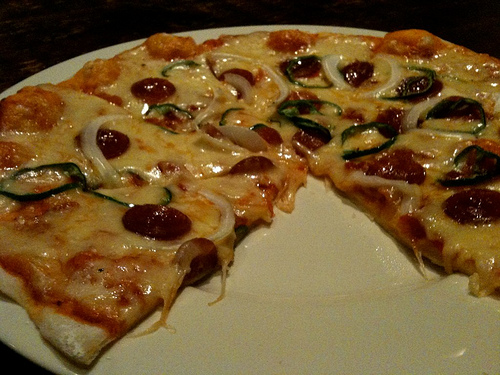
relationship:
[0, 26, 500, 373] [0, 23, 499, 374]
pizza on dinner plate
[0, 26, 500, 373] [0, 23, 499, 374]
pizza over dinner plate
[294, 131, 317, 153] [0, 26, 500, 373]
pepperoni on a pizza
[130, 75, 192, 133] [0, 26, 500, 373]
toppings on a pizza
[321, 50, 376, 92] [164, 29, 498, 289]
sliver onion on pizza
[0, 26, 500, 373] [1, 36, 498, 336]
pizza has cheese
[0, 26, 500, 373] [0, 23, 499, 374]
pizza on a dinner plate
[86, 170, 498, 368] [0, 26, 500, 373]
space in pizza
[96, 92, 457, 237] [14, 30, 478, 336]
cheese in pizza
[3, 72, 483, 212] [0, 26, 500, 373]
green peppers in pizza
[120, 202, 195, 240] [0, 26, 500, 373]
topping on pizza